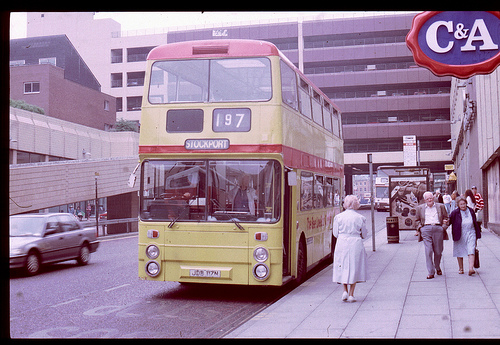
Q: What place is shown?
A: It is a street.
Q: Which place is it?
A: It is a street.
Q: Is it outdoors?
A: Yes, it is outdoors.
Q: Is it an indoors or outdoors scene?
A: It is outdoors.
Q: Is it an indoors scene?
A: No, it is outdoors.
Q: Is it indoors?
A: No, it is outdoors.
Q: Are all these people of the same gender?
A: No, they are both male and female.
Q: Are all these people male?
A: No, they are both male and female.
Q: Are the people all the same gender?
A: No, they are both male and female.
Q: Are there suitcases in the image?
A: No, there are no suitcases.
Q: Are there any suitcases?
A: No, there are no suitcases.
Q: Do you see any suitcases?
A: No, there are no suitcases.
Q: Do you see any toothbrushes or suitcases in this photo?
A: No, there are no suitcases or toothbrushes.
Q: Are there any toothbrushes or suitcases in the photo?
A: No, there are no suitcases or toothbrushes.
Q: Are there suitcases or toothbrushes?
A: No, there are no suitcases or toothbrushes.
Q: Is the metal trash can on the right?
A: Yes, the trashcan is on the right of the image.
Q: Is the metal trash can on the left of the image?
A: No, the garbage can is on the right of the image.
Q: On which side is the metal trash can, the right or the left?
A: The trashcan is on the right of the image.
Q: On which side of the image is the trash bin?
A: The trash bin is on the right of the image.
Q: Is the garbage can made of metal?
A: Yes, the garbage can is made of metal.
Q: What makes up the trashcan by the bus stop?
A: The trash can is made of metal.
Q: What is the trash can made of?
A: The trash can is made of metal.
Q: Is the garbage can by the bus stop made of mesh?
A: No, the trashcan is made of metal.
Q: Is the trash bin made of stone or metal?
A: The trash bin is made of metal.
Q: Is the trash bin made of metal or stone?
A: The trash bin is made of metal.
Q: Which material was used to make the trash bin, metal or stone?
A: The trash bin is made of metal.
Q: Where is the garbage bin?
A: The garbage bin is on the sidewalk.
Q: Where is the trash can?
A: The garbage bin is on the sidewalk.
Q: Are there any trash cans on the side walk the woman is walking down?
A: Yes, there is a trash can on the sidewalk.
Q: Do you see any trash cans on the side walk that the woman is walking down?
A: Yes, there is a trash can on the sidewalk.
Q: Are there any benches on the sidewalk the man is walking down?
A: No, there is a trash can on the sidewalk.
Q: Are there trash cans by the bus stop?
A: Yes, there is a trash can by the bus stop.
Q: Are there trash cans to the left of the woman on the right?
A: Yes, there is a trash can to the left of the woman.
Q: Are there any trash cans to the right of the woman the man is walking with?
A: No, the trash can is to the left of the woman.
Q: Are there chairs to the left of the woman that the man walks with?
A: No, there is a trash can to the left of the woman.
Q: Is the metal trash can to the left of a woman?
A: Yes, the garbage can is to the left of a woman.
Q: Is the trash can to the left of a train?
A: No, the trash can is to the left of a woman.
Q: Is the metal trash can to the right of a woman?
A: No, the trashcan is to the left of a woman.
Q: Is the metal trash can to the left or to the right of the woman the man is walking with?
A: The trashcan is to the left of the woman.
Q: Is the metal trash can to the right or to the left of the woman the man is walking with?
A: The trashcan is to the left of the woman.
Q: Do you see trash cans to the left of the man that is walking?
A: Yes, there is a trash can to the left of the man.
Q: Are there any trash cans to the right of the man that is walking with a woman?
A: No, the trash can is to the left of the man.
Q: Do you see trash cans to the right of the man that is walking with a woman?
A: No, the trash can is to the left of the man.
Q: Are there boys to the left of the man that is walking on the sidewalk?
A: No, there is a trash can to the left of the man.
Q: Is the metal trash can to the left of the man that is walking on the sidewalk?
A: Yes, the garbage bin is to the left of the man.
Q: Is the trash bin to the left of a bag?
A: No, the trash bin is to the left of the man.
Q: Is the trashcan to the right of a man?
A: No, the trashcan is to the left of a man.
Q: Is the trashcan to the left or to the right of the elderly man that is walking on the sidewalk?
A: The trashcan is to the left of the man.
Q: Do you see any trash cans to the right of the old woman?
A: Yes, there is a trash can to the right of the woman.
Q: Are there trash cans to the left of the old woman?
A: No, the trash can is to the right of the woman.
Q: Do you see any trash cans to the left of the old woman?
A: No, the trash can is to the right of the woman.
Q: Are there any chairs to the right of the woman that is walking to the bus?
A: No, there is a trash can to the right of the woman.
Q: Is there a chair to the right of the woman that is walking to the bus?
A: No, there is a trash can to the right of the woman.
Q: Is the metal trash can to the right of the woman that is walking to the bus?
A: Yes, the garbage bin is to the right of the woman.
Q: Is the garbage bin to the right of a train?
A: No, the garbage bin is to the right of the woman.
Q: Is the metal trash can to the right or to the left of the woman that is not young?
A: The trash bin is to the right of the woman.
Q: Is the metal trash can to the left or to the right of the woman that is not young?
A: The trash bin is to the right of the woman.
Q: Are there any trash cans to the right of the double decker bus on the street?
A: Yes, there is a trash can to the right of the bus.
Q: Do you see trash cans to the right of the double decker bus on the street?
A: Yes, there is a trash can to the right of the bus.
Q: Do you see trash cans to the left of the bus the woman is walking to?
A: No, the trash can is to the right of the bus.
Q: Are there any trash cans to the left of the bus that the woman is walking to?
A: No, the trash can is to the right of the bus.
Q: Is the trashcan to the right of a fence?
A: No, the trashcan is to the right of the bus.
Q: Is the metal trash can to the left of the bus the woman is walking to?
A: No, the garbage can is to the right of the bus.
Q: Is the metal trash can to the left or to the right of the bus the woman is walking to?
A: The garbage can is to the right of the bus.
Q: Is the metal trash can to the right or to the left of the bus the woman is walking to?
A: The garbage can is to the right of the bus.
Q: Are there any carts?
A: No, there are no carts.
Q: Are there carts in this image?
A: No, there are no carts.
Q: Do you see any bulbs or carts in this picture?
A: No, there are no carts or bulbs.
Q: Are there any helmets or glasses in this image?
A: No, there are no helmets or glasses.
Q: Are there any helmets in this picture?
A: No, there are no helmets.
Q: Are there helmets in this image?
A: No, there are no helmets.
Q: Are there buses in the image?
A: Yes, there is a bus.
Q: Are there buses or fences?
A: Yes, there is a bus.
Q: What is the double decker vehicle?
A: The vehicle is a bus.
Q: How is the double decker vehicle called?
A: The vehicle is a bus.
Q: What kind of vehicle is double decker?
A: The vehicle is a bus.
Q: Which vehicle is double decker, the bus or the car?
A: The bus is double decker.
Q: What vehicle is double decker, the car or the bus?
A: The bus is double decker.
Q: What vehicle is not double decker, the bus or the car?
A: The car is not double decker.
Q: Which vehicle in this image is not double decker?
A: The vehicle is a car.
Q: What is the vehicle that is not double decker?
A: The vehicle is a car.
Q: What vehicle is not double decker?
A: The vehicle is a car.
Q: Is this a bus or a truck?
A: This is a bus.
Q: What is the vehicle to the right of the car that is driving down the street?
A: The vehicle is a bus.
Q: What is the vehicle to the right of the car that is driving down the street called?
A: The vehicle is a bus.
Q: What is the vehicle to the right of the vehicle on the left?
A: The vehicle is a bus.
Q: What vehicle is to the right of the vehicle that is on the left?
A: The vehicle is a bus.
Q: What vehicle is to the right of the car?
A: The vehicle is a bus.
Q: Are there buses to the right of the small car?
A: Yes, there is a bus to the right of the car.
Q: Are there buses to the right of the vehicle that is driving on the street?
A: Yes, there is a bus to the right of the car.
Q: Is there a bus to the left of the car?
A: No, the bus is to the right of the car.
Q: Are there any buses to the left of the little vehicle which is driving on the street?
A: No, the bus is to the right of the car.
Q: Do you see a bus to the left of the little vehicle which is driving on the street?
A: No, the bus is to the right of the car.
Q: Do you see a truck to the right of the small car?
A: No, there is a bus to the right of the car.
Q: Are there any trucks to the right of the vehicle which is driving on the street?
A: No, there is a bus to the right of the car.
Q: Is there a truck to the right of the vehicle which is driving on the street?
A: No, there is a bus to the right of the car.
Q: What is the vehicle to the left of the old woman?
A: The vehicle is a bus.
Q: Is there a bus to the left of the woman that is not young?
A: Yes, there is a bus to the left of the woman.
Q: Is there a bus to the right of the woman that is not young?
A: No, the bus is to the left of the woman.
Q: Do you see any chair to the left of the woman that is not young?
A: No, there is a bus to the left of the woman.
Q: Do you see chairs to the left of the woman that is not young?
A: No, there is a bus to the left of the woman.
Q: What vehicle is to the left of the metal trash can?
A: The vehicle is a bus.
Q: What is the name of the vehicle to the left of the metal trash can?
A: The vehicle is a bus.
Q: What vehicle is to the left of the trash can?
A: The vehicle is a bus.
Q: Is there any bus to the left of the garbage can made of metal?
A: Yes, there is a bus to the left of the trash bin.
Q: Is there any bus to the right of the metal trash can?
A: No, the bus is to the left of the trash bin.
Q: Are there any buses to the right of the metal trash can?
A: No, the bus is to the left of the trash bin.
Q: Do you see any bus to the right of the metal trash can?
A: No, the bus is to the left of the trash bin.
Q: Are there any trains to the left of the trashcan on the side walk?
A: No, there is a bus to the left of the trash bin.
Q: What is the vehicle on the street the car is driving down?
A: The vehicle is a bus.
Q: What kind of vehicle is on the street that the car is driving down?
A: The vehicle is a bus.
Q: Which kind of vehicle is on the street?
A: The vehicle is a bus.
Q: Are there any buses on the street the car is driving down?
A: Yes, there is a bus on the street.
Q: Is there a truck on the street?
A: No, there is a bus on the street.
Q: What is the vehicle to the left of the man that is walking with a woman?
A: The vehicle is a bus.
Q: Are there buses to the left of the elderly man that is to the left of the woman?
A: Yes, there is a bus to the left of the man.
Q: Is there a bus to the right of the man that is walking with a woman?
A: No, the bus is to the left of the man.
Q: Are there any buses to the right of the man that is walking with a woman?
A: No, the bus is to the left of the man.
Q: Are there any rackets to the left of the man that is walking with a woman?
A: No, there is a bus to the left of the man.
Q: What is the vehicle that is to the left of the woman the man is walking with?
A: The vehicle is a bus.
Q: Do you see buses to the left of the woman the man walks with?
A: Yes, there is a bus to the left of the woman.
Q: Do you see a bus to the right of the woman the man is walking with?
A: No, the bus is to the left of the woman.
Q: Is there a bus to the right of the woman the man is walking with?
A: No, the bus is to the left of the woman.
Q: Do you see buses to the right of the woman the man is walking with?
A: No, the bus is to the left of the woman.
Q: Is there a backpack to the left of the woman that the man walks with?
A: No, there is a bus to the left of the woman.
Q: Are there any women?
A: Yes, there is a woman.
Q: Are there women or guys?
A: Yes, there is a woman.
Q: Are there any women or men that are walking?
A: Yes, the woman is walking.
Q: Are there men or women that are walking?
A: Yes, the woman is walking.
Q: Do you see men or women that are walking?
A: Yes, the woman is walking.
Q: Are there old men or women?
A: Yes, there is an old woman.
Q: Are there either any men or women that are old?
A: Yes, the woman is old.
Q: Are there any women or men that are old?
A: Yes, the woman is old.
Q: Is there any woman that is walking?
A: Yes, there is a woman that is walking.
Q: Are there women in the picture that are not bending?
A: Yes, there is a woman that is walking.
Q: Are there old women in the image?
A: Yes, there is an old woman.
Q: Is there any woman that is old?
A: Yes, there is a woman that is old.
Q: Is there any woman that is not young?
A: Yes, there is a old woman.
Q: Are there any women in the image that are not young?
A: Yes, there is a old woman.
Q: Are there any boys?
A: No, there are no boys.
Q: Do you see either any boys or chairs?
A: No, there are no boys or chairs.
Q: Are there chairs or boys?
A: No, there are no boys or chairs.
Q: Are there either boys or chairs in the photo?
A: No, there are no boys or chairs.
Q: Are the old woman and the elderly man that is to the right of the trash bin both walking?
A: Yes, both the woman and the man are walking.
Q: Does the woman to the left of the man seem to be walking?
A: Yes, the woman is walking.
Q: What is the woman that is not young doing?
A: The woman is walking.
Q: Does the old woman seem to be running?
A: No, the woman is walking.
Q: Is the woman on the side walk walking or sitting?
A: The woman is walking.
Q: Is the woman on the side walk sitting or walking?
A: The woman is walking.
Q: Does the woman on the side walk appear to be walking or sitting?
A: The woman is walking.